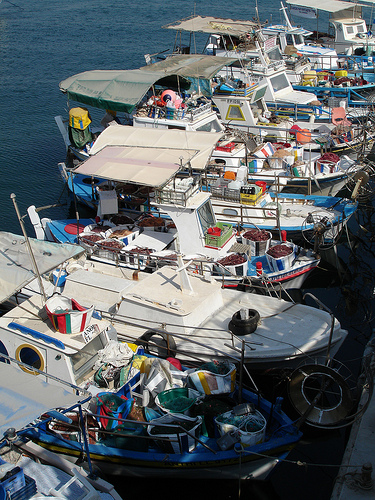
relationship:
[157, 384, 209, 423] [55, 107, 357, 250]
basket on a boat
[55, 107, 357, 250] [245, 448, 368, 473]
boat has a rope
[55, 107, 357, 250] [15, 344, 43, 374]
boat has a window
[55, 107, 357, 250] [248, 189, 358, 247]
boat has a front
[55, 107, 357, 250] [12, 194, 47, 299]
boat has an antenna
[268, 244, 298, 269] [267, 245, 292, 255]
box has lobsters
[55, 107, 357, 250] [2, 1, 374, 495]
boat near water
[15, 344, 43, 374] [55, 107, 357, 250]
window in a boat